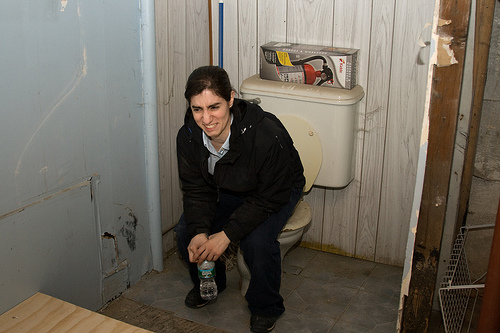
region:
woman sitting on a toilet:
[170, 65, 305, 332]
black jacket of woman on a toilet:
[175, 121, 295, 231]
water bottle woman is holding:
[195, 245, 217, 302]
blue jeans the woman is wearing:
[175, 193, 291, 316]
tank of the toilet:
[247, 79, 364, 191]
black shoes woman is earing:
[186, 285, 282, 332]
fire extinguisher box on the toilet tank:
[261, 41, 353, 83]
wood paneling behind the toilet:
[155, 1, 418, 252]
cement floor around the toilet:
[136, 229, 401, 331]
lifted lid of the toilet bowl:
[274, 110, 318, 197]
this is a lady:
[147, 68, 286, 263]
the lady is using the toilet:
[159, 57, 285, 289]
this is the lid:
[297, 132, 317, 164]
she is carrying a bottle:
[190, 247, 221, 301]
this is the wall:
[371, 129, 414, 188]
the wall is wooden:
[382, 14, 426, 71]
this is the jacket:
[241, 147, 294, 207]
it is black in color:
[243, 135, 292, 187]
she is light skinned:
[213, 106, 227, 118]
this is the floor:
[319, 267, 386, 332]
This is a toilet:
[255, 55, 365, 263]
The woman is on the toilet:
[157, 53, 313, 323]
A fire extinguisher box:
[250, 31, 367, 94]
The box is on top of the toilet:
[237, 24, 375, 82]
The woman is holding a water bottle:
[189, 222, 224, 297]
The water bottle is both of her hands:
[180, 229, 242, 302]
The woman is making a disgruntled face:
[185, 73, 237, 147]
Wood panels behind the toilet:
[223, 5, 415, 244]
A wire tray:
[432, 217, 487, 329]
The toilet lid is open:
[291, 108, 325, 190]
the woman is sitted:
[163, 78, 317, 332]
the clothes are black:
[166, 117, 295, 318]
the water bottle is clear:
[183, 261, 223, 302]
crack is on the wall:
[98, 223, 133, 251]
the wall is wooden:
[375, 50, 422, 186]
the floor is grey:
[303, 268, 358, 313]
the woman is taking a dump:
[160, 75, 326, 330]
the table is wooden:
[20, 288, 81, 329]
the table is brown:
[12, 295, 87, 331]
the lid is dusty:
[251, 77, 371, 97]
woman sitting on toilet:
[178, 66, 305, 327]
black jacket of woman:
[178, 108, 304, 233]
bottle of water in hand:
[194, 255, 217, 295]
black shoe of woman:
[248, 312, 290, 331]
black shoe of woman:
[188, 288, 209, 303]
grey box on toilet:
[256, 45, 358, 90]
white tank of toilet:
[241, 75, 364, 184]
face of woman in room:
[181, 70, 237, 138]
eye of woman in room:
[190, 105, 201, 112]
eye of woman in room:
[208, 101, 220, 111]